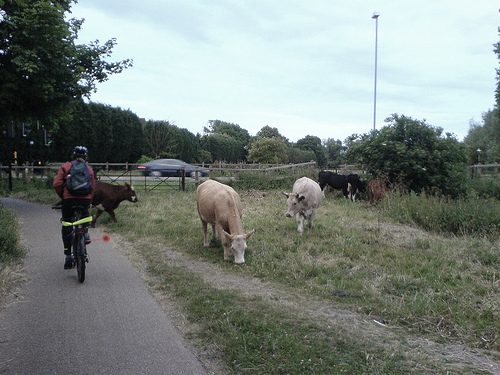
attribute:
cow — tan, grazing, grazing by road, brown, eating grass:
[193, 176, 255, 266]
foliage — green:
[12, 172, 499, 374]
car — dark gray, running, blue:
[134, 154, 214, 177]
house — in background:
[1, 97, 63, 172]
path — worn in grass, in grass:
[150, 232, 495, 370]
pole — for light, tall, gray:
[367, 7, 382, 135]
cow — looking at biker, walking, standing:
[278, 173, 327, 237]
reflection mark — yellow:
[60, 213, 94, 227]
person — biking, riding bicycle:
[53, 144, 95, 269]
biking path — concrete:
[1, 195, 210, 374]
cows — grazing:
[192, 166, 370, 267]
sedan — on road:
[133, 154, 213, 180]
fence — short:
[1, 159, 325, 196]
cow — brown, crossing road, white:
[55, 177, 141, 230]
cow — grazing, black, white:
[343, 169, 369, 203]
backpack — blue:
[65, 157, 94, 195]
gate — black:
[88, 160, 189, 196]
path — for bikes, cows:
[1, 193, 210, 373]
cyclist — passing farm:
[51, 142, 100, 283]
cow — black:
[315, 165, 350, 203]